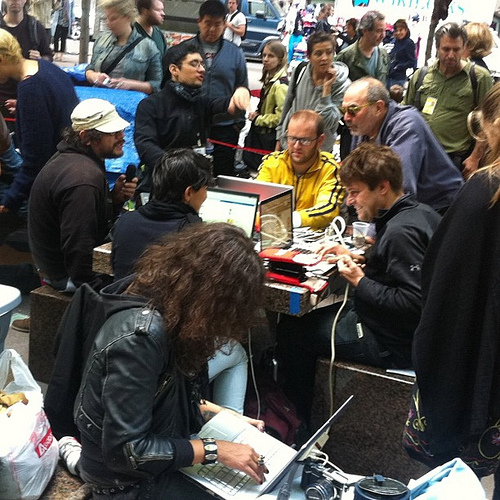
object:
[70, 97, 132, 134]
hat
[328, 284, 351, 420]
cord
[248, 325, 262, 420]
cord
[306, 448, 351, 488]
cord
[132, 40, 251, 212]
man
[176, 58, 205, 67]
eye glasses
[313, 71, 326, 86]
sand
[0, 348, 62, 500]
plastic bag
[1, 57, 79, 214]
sweater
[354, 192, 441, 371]
jacket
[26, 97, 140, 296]
man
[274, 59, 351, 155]
hoodie